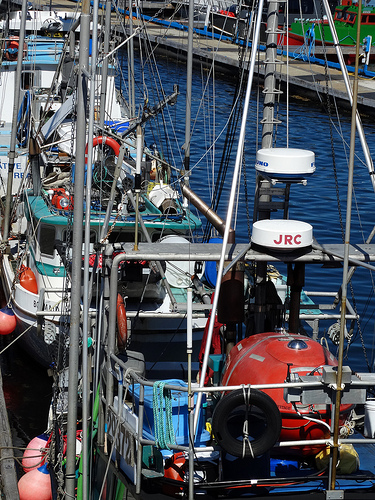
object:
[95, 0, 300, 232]
wires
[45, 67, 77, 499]
chain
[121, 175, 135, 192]
life wheel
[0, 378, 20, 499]
dock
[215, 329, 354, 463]
engine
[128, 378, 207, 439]
tub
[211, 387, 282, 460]
tire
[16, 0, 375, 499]
boat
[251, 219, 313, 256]
disk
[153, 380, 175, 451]
rope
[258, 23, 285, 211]
mast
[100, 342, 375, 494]
railing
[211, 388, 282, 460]
chord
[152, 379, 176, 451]
container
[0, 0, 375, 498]
boats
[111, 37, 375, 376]
water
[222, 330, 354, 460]
ball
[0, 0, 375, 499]
bouys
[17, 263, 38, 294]
tank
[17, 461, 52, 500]
boat anchor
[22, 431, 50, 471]
boat anchor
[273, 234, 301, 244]
letters